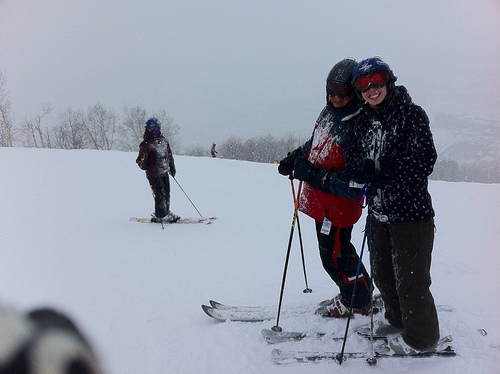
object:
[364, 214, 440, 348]
pants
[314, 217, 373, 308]
pants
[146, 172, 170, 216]
pants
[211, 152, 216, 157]
pants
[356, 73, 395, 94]
goggles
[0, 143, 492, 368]
snow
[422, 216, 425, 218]
white dot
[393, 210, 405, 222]
dot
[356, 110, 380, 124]
dot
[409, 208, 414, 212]
dot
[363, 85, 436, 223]
coat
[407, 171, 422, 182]
dot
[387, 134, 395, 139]
dot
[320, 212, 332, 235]
lift pass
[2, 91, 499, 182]
trees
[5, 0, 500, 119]
sky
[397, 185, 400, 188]
white dot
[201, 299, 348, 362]
skis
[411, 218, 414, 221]
white dot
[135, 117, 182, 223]
person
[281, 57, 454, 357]
people